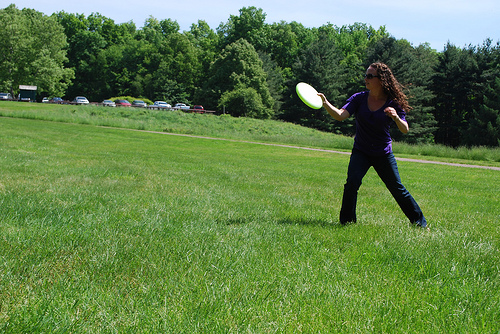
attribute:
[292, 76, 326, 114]
frisbee — green, white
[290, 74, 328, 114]
frisbee — green, yellow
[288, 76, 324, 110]
frisbee — green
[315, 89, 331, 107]
hand — green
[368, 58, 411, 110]
hair — curly, long, woman's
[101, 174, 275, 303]
grass — deep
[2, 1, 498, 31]
sky — blue, cloudless 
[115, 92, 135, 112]
car — red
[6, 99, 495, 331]
grass — green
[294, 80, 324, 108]
frisbee — green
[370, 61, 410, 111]
hair — woman's, dark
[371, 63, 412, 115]
hair — woman's, long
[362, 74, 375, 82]
glasses — dark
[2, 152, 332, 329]
grass — green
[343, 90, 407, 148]
shirt — woman's, purple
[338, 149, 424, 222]
pants — woman's, blue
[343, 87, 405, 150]
shirt — purple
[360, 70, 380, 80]
sunglasses — black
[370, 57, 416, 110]
hair — long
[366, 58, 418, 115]
hair — brown